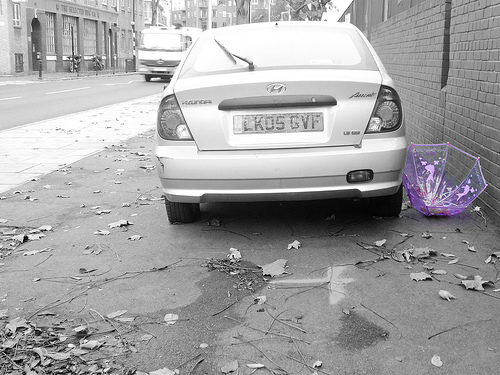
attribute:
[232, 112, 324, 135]
license plate — white, black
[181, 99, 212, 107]
logo — silver, hyundai car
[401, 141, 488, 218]
umbrella — pink, purple, opened, upside down, transparent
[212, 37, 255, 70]
wiper blade — black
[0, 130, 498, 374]
leaves — dead, fallen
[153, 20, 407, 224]
car — parked, light-colored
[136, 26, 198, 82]
truck — black, white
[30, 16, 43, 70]
archway — small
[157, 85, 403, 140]
tail lights — round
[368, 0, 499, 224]
wall — brick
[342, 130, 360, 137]
lettering — black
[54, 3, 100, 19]
lettering — black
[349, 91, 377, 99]
lettering — black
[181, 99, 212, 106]
lettering — black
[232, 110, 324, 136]
lettering — black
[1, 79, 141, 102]
stripe — white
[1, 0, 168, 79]
building — old